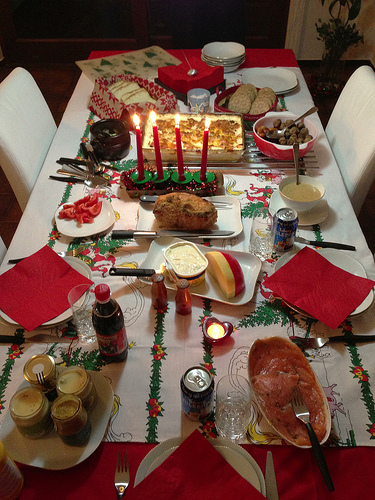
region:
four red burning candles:
[127, 112, 216, 187]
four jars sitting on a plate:
[12, 348, 104, 458]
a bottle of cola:
[85, 279, 143, 368]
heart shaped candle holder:
[199, 311, 233, 350]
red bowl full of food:
[249, 112, 326, 160]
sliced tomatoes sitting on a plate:
[54, 190, 116, 237]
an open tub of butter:
[160, 233, 206, 287]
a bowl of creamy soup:
[271, 150, 333, 222]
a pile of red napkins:
[154, 56, 225, 90]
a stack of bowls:
[200, 38, 249, 72]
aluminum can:
[170, 364, 220, 425]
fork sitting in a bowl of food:
[246, 336, 344, 495]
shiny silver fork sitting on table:
[108, 449, 138, 498]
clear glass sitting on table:
[214, 375, 252, 442]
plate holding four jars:
[6, 345, 110, 475]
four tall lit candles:
[123, 105, 224, 188]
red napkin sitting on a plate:
[263, 246, 373, 336]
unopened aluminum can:
[272, 207, 298, 246]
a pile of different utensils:
[49, 142, 121, 190]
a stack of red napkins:
[152, 49, 225, 100]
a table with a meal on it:
[0, 47, 374, 498]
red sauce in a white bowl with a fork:
[245, 330, 338, 445]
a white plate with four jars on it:
[8, 350, 113, 462]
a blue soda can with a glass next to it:
[176, 362, 252, 443]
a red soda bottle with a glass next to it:
[70, 276, 136, 360]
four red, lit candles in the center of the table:
[114, 109, 230, 196]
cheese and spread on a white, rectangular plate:
[130, 233, 261, 301]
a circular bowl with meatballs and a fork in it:
[258, 109, 319, 154]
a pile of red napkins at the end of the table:
[158, 51, 227, 92]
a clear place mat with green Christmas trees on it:
[75, 43, 180, 81]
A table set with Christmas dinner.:
[37, 76, 347, 459]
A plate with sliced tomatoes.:
[49, 193, 124, 246]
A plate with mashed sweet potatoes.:
[246, 333, 335, 451]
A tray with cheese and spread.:
[139, 229, 262, 309]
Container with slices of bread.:
[91, 67, 175, 128]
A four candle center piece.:
[122, 108, 233, 198]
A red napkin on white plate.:
[263, 242, 373, 322]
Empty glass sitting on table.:
[214, 368, 258, 444]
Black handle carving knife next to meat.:
[107, 225, 242, 240]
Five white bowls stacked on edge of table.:
[195, 38, 250, 73]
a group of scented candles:
[14, 352, 104, 455]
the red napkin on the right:
[260, 237, 371, 333]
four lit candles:
[122, 103, 224, 194]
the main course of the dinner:
[141, 191, 251, 243]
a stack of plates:
[196, 35, 247, 71]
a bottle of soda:
[85, 263, 140, 375]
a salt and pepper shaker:
[143, 265, 201, 316]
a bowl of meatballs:
[248, 100, 324, 163]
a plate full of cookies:
[211, 78, 283, 122]